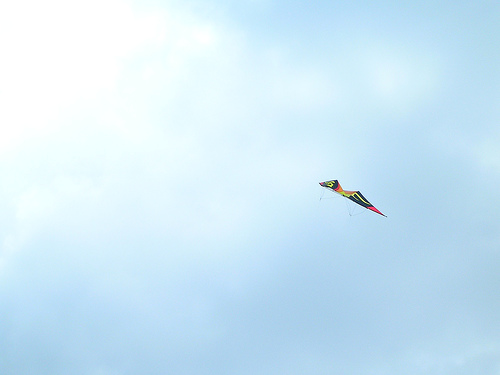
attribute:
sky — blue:
[8, 63, 498, 356]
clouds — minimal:
[27, 120, 299, 290]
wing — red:
[349, 179, 394, 221]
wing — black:
[340, 186, 386, 221]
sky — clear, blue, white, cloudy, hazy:
[5, 2, 497, 372]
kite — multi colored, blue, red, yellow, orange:
[314, 162, 391, 224]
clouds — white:
[2, 2, 157, 129]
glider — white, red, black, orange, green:
[308, 174, 391, 223]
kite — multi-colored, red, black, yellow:
[314, 171, 384, 223]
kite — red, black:
[303, 165, 387, 224]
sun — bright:
[9, 3, 500, 314]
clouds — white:
[3, 2, 166, 172]